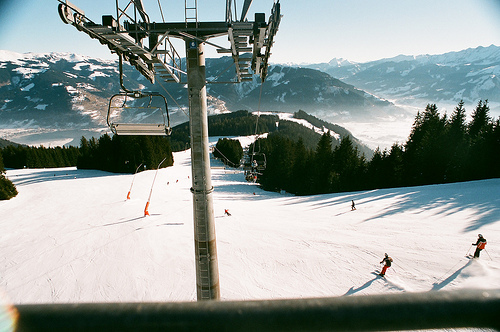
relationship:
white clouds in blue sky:
[0, 0, 499, 66] [315, 6, 419, 41]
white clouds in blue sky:
[338, 2, 425, 40] [335, 5, 434, 41]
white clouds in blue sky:
[0, 0, 499, 66] [0, 0, 498, 66]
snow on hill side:
[0, 176, 499, 332] [331, 206, 467, 250]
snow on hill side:
[53, 248, 133, 296] [25, 236, 113, 279]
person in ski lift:
[240, 152, 261, 173] [236, 146, 267, 196]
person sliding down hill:
[340, 196, 366, 224] [297, 204, 334, 259]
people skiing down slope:
[365, 250, 498, 270] [284, 221, 327, 252]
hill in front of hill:
[56, 49, 382, 120] [0, 50, 415, 129]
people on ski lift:
[376, 252, 395, 278] [241, 150, 271, 178]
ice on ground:
[0, 106, 499, 305] [276, 258, 323, 301]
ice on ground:
[92, 252, 192, 314] [48, 244, 99, 276]